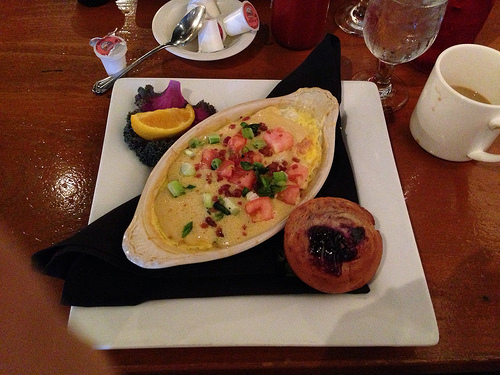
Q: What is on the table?
A: Food.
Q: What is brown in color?
A: Table.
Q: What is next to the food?
A: Drink.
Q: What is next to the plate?
A: A spoon.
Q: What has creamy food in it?
A: Oval dish.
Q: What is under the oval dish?
A: Black napkin.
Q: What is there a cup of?
A: Coffee.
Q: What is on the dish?
A: Food.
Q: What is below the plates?
A: The table.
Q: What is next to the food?
A: Drinks.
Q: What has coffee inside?
A: Coffee cup.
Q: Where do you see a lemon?
A: On the white plate.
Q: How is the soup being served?
A: In a long bowl.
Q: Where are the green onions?
A: In the soup dish.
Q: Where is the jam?
A: On toast.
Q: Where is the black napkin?
A: Under the plate.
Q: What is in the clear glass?
A: Water.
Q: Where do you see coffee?
A: In the white cup.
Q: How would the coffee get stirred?
A: With the spoon.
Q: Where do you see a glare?
A: On the table.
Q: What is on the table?
A: Food.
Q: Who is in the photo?
A: Nobody.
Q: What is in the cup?
A: A drink.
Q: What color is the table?
A: Brown.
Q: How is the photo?
A: Clear.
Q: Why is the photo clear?
A: The area is lit.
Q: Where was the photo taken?
A: Close to food.